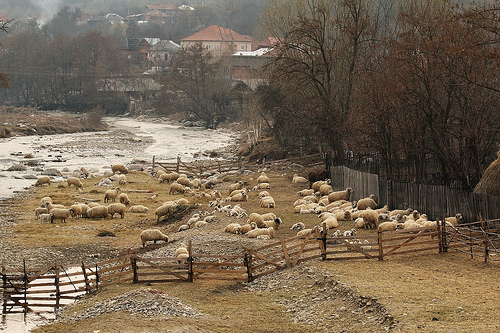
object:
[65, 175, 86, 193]
sheep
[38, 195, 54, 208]
sheep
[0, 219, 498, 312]
fence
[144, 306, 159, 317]
stone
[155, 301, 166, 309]
stone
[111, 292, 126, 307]
stone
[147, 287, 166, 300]
stone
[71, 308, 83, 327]
stone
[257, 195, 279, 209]
sheep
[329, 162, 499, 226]
fence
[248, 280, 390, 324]
rocks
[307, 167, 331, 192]
horse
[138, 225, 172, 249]
sheep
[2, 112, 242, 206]
river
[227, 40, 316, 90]
houses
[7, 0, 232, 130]
trees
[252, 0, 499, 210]
trees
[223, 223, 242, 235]
sheep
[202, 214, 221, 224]
sheep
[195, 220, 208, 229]
sheep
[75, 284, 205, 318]
pile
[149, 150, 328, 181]
fence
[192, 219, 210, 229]
lamb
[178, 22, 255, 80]
buildings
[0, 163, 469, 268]
pen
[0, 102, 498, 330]
ground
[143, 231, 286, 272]
rocks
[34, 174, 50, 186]
lamb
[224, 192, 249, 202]
sheep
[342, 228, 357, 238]
sheep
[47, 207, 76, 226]
sheep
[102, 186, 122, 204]
sheep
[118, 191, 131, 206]
sheep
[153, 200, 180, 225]
sheep